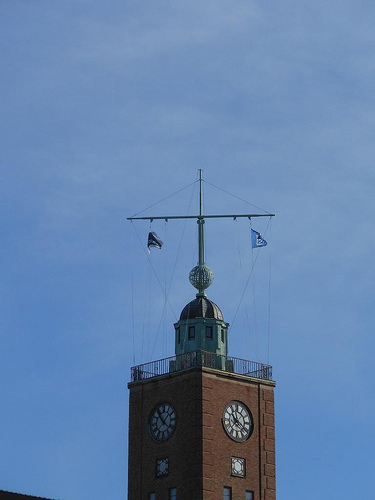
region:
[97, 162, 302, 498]
tall clock tower building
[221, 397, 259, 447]
clock on a tower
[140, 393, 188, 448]
clock telling the time of 11:20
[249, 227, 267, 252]
blue flag above tower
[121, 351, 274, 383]
metal railing on top of tower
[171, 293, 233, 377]
dome ceiling section of tower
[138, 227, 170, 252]
black flag on building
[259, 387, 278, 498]
brick design on side of building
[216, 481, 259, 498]
windows of the tower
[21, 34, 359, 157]
blue sky in the background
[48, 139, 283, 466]
a building with a clock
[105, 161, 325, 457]
a building with two flags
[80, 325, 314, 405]
a building with an area to walk at the top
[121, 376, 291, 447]
a building with two clocks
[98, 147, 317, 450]
a building during the day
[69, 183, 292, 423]
a building against clear skies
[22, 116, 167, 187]
clear sky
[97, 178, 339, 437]
a building with two flags and two clocks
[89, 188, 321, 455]
an old building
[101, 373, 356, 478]
an old building with clocks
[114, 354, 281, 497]
the clocks are on the tower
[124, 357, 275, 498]
the tower is brick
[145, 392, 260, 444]
the clock faces are black and white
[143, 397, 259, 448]
the numbers are roman numerals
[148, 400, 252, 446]
the numbers are black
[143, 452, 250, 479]
the windows are square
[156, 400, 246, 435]
the hands on the clocks are black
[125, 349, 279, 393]
the railing is above the clocks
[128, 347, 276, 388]
the railing is on top of the building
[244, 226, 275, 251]
the flag is blue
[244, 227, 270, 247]
Blue flag against a blue sky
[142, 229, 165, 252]
Black flag against a blue sky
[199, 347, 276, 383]
Metal fence around top of brick building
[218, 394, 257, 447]
Clock face in a brick building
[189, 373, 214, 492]
Corner of a brick building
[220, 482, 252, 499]
Two windows on the side of a brick building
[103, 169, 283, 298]
Mast on the top of a building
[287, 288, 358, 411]
Clear blue sky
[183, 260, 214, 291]
Metal circle at the base of a pole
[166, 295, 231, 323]
Domed roof on top of a building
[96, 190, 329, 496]
Large brown clock tower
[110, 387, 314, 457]
Two clock faces on clock tower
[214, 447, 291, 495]
Decorative window on clock tower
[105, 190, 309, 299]
Two flags flying on top of clock tower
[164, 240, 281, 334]
Green metal decorative globe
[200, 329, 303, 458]
Metal fence around roof of clock tower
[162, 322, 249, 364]
4 rectangular windows on tower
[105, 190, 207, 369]
Several securing cables on tower top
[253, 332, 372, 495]
clear blue open sky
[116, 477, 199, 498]
Two small rectangular windows on left side of tower